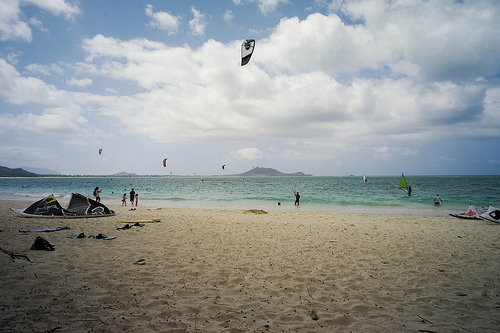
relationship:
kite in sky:
[239, 35, 256, 67] [1, 1, 500, 174]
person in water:
[435, 194, 441, 205] [0, 174, 500, 222]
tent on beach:
[14, 191, 116, 219] [2, 197, 500, 330]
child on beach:
[136, 195, 140, 205] [2, 197, 500, 330]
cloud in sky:
[256, 10, 385, 71] [1, 1, 500, 174]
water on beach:
[0, 174, 500, 222] [2, 197, 500, 330]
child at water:
[136, 195, 140, 205] [0, 174, 500, 222]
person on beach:
[435, 194, 441, 205] [2, 197, 500, 330]